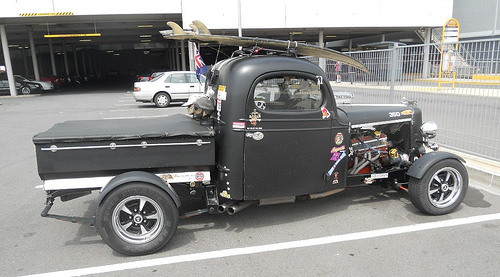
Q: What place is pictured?
A: It is a pavement.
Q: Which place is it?
A: It is a pavement.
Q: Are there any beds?
A: Yes, there is a bed.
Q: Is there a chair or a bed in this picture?
A: Yes, there is a bed.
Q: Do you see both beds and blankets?
A: No, there is a bed but no blankets.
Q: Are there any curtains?
A: No, there are no curtains.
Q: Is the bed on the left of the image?
A: Yes, the bed is on the left of the image.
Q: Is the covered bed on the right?
A: No, the bed is on the left of the image.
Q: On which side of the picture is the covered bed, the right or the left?
A: The bed is on the left of the image.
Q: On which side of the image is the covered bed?
A: The bed is on the left of the image.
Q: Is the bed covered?
A: Yes, the bed is covered.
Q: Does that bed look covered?
A: Yes, the bed is covered.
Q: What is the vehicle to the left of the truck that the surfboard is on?
A: The vehicle is a car.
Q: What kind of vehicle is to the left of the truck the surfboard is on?
A: The vehicle is a car.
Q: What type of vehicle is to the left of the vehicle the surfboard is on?
A: The vehicle is a car.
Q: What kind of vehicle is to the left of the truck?
A: The vehicle is a car.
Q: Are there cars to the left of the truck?
A: Yes, there is a car to the left of the truck.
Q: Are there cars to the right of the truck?
A: No, the car is to the left of the truck.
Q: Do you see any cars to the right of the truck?
A: No, the car is to the left of the truck.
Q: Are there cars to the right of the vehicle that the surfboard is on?
A: No, the car is to the left of the truck.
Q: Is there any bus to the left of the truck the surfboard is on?
A: No, there is a car to the left of the truck.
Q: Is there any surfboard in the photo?
A: Yes, there is a surfboard.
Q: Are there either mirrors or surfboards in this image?
A: Yes, there is a surfboard.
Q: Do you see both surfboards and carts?
A: No, there is a surfboard but no carts.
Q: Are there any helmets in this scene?
A: No, there are no helmets.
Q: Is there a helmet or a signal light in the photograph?
A: No, there are no helmets or traffic lights.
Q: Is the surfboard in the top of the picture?
A: Yes, the surfboard is in the top of the image.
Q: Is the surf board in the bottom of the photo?
A: No, the surf board is in the top of the image.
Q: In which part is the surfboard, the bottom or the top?
A: The surfboard is in the top of the image.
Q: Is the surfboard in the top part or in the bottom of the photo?
A: The surfboard is in the top of the image.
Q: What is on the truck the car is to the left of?
A: The surfboard is on the truck.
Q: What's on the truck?
A: The surfboard is on the truck.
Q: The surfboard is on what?
A: The surfboard is on the truck.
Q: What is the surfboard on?
A: The surfboard is on the truck.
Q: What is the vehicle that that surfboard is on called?
A: The vehicle is a truck.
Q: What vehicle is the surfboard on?
A: The surfboard is on the truck.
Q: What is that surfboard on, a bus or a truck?
A: The surfboard is on a truck.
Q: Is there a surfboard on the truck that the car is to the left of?
A: Yes, there is a surfboard on the truck.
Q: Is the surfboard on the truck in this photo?
A: Yes, the surfboard is on the truck.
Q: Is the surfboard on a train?
A: No, the surfboard is on the truck.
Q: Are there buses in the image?
A: No, there are no buses.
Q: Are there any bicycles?
A: No, there are no bicycles.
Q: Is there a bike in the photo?
A: No, there are no bikes.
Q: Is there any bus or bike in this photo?
A: No, there are no bikes or buses.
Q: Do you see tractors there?
A: No, there are no tractors.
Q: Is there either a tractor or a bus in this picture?
A: No, there are no tractors or buses.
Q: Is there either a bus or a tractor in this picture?
A: No, there are no tractors or buses.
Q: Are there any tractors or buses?
A: No, there are no tractors or buses.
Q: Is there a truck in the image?
A: Yes, there is a truck.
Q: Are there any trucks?
A: Yes, there is a truck.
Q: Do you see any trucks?
A: Yes, there is a truck.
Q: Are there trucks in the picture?
A: Yes, there is a truck.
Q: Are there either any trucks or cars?
A: Yes, there is a truck.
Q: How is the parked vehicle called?
A: The vehicle is a truck.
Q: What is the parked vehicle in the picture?
A: The vehicle is a truck.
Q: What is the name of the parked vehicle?
A: The vehicle is a truck.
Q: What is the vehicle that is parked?
A: The vehicle is a truck.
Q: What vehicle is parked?
A: The vehicle is a truck.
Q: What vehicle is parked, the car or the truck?
A: The truck is parked.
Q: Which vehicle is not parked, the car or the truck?
A: The car is not parked.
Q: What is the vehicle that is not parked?
A: The vehicle is a car.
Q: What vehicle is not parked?
A: The vehicle is a car.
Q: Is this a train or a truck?
A: This is a truck.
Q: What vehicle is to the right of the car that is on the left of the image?
A: The vehicle is a truck.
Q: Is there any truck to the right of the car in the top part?
A: Yes, there is a truck to the right of the car.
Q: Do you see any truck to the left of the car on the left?
A: No, the truck is to the right of the car.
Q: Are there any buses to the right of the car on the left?
A: No, there is a truck to the right of the car.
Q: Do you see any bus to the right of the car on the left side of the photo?
A: No, there is a truck to the right of the car.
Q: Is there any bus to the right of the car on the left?
A: No, there is a truck to the right of the car.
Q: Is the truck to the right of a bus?
A: No, the truck is to the right of a car.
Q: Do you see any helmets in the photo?
A: No, there are no helmets.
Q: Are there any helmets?
A: No, there are no helmets.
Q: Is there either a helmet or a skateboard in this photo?
A: No, there are no helmets or skateboards.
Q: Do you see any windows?
A: Yes, there is a window.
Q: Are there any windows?
A: Yes, there is a window.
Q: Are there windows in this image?
A: Yes, there is a window.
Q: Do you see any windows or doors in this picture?
A: Yes, there is a window.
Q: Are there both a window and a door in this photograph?
A: Yes, there are both a window and a door.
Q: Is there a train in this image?
A: No, there are no trains.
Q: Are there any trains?
A: No, there are no trains.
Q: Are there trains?
A: No, there are no trains.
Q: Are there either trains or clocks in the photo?
A: No, there are no trains or clocks.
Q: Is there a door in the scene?
A: Yes, there is a door.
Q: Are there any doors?
A: Yes, there is a door.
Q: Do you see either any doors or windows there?
A: Yes, there is a door.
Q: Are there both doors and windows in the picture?
A: Yes, there are both a door and windows.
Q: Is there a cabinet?
A: No, there are no cabinets.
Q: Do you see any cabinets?
A: No, there are no cabinets.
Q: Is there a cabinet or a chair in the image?
A: No, there are no cabinets or chairs.